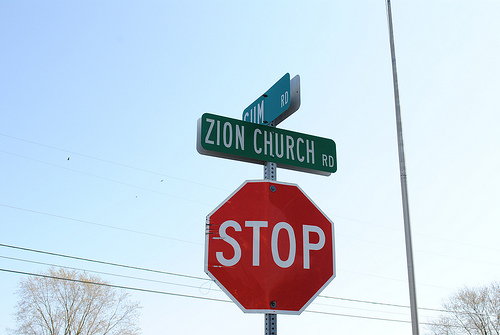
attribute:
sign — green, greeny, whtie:
[192, 69, 348, 181]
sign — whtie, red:
[192, 170, 338, 325]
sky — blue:
[69, 25, 84, 53]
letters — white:
[212, 118, 345, 158]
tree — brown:
[23, 264, 110, 329]